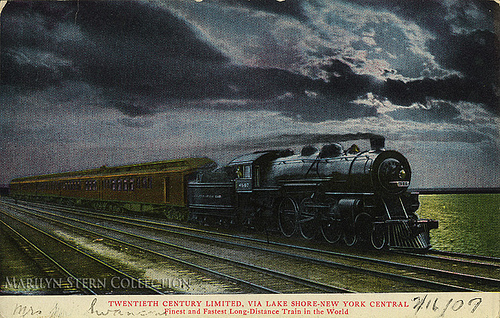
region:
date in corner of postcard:
[406, 285, 485, 316]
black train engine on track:
[182, 130, 445, 260]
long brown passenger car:
[6, 151, 211, 216]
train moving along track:
[2, 129, 443, 264]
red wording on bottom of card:
[105, 287, 414, 315]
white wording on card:
[3, 268, 196, 298]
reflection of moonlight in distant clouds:
[291, 39, 438, 129]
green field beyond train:
[414, 185, 499, 261]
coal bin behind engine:
[182, 162, 240, 222]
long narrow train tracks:
[2, 196, 498, 296]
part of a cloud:
[408, 70, 422, 82]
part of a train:
[330, 164, 337, 176]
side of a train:
[311, 180, 321, 200]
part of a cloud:
[286, 115, 296, 134]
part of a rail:
[116, 228, 137, 247]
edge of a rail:
[168, 197, 183, 230]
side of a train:
[218, 172, 235, 186]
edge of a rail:
[194, 200, 210, 232]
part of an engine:
[317, 147, 324, 162]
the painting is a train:
[36, 76, 463, 286]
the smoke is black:
[303, 98, 428, 211]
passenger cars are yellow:
[39, 136, 494, 258]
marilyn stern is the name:
[3, 252, 125, 306]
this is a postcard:
[20, 11, 392, 301]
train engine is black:
[183, 128, 438, 245]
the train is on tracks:
[66, 51, 442, 303]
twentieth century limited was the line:
[65, 265, 430, 310]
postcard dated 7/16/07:
[391, 278, 487, 312]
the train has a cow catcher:
[251, 112, 461, 270]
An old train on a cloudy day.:
[7, 135, 437, 251]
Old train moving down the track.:
[7, 132, 438, 251]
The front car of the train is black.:
[228, 133, 436, 254]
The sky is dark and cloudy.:
[0, 0, 496, 185]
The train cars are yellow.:
[5, 155, 210, 205]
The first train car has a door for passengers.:
[162, 172, 167, 198]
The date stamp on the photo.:
[410, 292, 480, 312]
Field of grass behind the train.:
[417, 190, 497, 255]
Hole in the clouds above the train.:
[327, 10, 443, 75]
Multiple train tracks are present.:
[0, 196, 499, 288]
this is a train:
[133, 122, 426, 224]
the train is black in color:
[193, 120, 417, 225]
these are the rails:
[155, 227, 225, 272]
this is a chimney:
[369, 134, 385, 149]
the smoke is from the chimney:
[353, 125, 374, 137]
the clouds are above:
[152, 2, 279, 92]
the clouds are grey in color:
[110, 27, 187, 101]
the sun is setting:
[363, 60, 393, 85]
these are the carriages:
[110, 163, 187, 205]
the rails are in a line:
[145, 223, 196, 253]